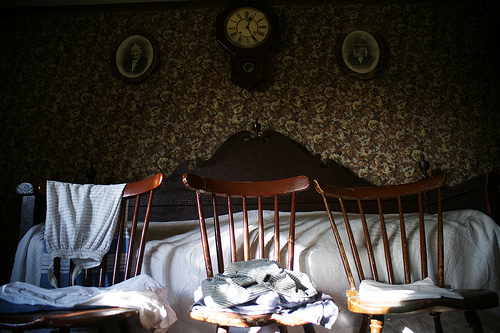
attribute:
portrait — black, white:
[111, 29, 158, 83]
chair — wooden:
[182, 175, 325, 330]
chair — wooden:
[12, 175, 165, 329]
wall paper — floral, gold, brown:
[3, 12, 498, 184]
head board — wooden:
[101, 126, 409, 210]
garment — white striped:
[40, 176, 120, 269]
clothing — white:
[4, 280, 195, 321]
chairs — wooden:
[9, 176, 478, 315]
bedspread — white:
[17, 211, 495, 325]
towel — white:
[355, 277, 446, 299]